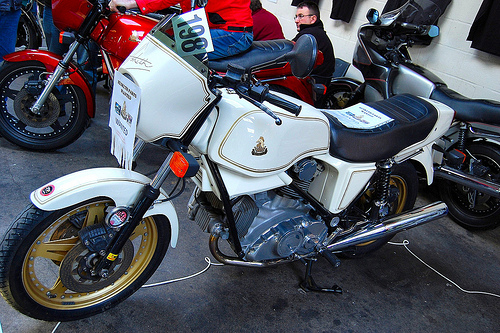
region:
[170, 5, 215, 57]
White tag that says 198.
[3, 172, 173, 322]
A front wheel with black and gold on it.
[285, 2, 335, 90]
A sitting man in black with glasses.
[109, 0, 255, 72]
A person in a bright red shirt and blue jeans.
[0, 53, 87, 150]
Front black wheel under a red fender.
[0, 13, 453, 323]
White and black bike with a gold inside wheel.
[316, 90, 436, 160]
Black seat on a white bike with a note on the seat.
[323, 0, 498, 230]
A grey and black bike up against the wall.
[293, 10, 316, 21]
Glasses on a man's face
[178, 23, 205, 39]
Black number 9 by the 1 and 8.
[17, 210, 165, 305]
Front tire on bike is black.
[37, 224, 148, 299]
Gold rim on front of bike.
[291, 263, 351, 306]
Black kickstand is down on bike.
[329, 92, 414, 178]
Black seat on bike.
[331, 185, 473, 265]
Silver exhaust on bike.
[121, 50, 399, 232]
Bike is white in color.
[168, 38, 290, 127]
Black handle bars on bike.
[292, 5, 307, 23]
Man wearing glasses on face.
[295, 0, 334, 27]
Man has dark hair.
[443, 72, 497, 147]
Black seat on silver bike.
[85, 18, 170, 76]
motorbike is red and shiny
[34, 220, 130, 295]
motorbike has gold wheel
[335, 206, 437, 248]
chrome exhaust pipe on motorbike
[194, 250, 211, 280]
white cord on ground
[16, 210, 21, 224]
black tire of motorbike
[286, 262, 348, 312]
motorbike with dark kickstand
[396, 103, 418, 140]
black seat of motorbike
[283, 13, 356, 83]
man wearing framed glasses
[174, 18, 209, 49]
white and black sign on motorbike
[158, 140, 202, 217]
red turn signal on motorbike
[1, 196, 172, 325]
black and gold motorcycle wheel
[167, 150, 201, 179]
orange and blue motorcycle light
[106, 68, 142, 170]
white sign on a motorcycle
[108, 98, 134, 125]
graphic on a white sign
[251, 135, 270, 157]
gold logo on a white motorcycle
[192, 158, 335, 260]
engine of a motorcycle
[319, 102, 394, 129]
white paper on a motorcycle seat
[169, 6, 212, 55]
label with a number print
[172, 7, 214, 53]
label reading 198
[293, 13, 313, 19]
glasses on a man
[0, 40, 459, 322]
a motorcycle parked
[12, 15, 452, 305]
a black and white motorcycle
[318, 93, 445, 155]
a black motorcycle seat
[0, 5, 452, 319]
a red motorcycle behind a white motorcyle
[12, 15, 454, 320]
a motorcycle facing left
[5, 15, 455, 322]
a motorcycle standing upright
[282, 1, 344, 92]
a man with glasses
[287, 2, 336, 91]
a man wearing a black jacket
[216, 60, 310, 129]
a black motorcycle handlebar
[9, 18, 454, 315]
a motorcycle in the parking lot